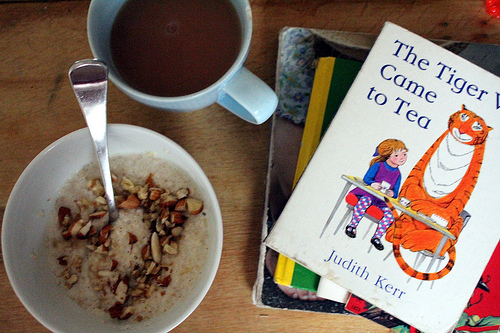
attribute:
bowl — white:
[19, 106, 226, 330]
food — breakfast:
[42, 150, 218, 323]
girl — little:
[348, 128, 395, 268]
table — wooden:
[2, 2, 497, 329]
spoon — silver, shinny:
[51, 47, 145, 210]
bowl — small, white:
[0, 122, 225, 332]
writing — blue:
[363, 36, 486, 137]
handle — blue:
[218, 71, 282, 141]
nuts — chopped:
[133, 182, 183, 233]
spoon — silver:
[69, 61, 116, 213]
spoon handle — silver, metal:
[68, 58, 120, 220]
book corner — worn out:
[271, 17, 327, 99]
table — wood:
[7, 4, 407, 331]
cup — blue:
[79, 3, 278, 125]